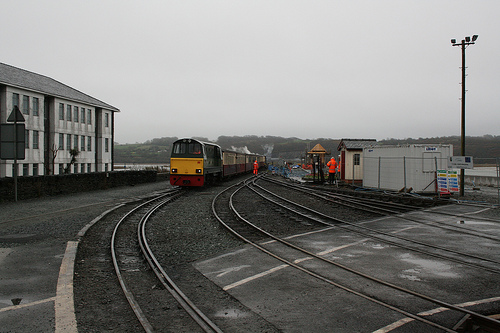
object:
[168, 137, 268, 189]
train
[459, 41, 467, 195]
pole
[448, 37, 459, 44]
lights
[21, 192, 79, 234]
ground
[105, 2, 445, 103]
sky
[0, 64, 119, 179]
building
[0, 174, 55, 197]
fence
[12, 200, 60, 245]
areas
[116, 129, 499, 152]
hills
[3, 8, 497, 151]
background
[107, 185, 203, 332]
track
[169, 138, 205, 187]
front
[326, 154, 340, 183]
person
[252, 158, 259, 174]
jacket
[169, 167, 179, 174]
headlights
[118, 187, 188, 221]
sets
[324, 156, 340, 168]
top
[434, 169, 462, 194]
sign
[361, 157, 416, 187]
fence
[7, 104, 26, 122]
sign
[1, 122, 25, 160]
back side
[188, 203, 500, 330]
crossing area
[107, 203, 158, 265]
pair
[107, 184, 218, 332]
tracks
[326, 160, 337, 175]
coat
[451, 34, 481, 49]
set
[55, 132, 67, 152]
window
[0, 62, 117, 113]
roof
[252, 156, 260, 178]
worker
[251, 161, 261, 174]
orange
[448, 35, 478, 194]
flood lights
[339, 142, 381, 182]
shed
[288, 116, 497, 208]
side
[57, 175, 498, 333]
trainyard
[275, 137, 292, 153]
trees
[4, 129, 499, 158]
distance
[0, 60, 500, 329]
building and tracks